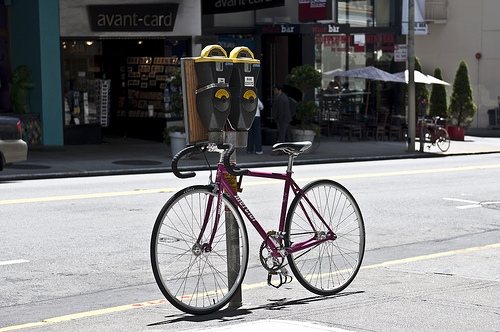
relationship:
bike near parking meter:
[149, 138, 367, 317] [192, 42, 263, 309]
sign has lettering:
[84, 2, 180, 33] [97, 14, 173, 29]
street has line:
[1, 150, 499, 329] [0, 162, 499, 205]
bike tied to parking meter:
[149, 138, 367, 317] [192, 42, 263, 309]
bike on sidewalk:
[149, 138, 367, 317] [2, 238, 499, 329]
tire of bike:
[284, 178, 366, 297] [149, 138, 367, 317]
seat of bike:
[273, 138, 314, 155] [149, 138, 367, 317]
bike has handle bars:
[149, 138, 367, 317] [171, 140, 251, 178]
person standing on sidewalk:
[269, 84, 296, 154] [0, 125, 499, 179]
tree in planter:
[446, 60, 476, 127] [444, 124, 469, 141]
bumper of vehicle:
[0, 139, 30, 168] [0, 115, 31, 172]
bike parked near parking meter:
[149, 138, 367, 317] [192, 42, 263, 309]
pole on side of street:
[406, 0, 418, 157] [1, 150, 499, 329]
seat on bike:
[273, 138, 314, 155] [149, 138, 367, 317]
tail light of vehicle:
[16, 120, 25, 136] [0, 115, 31, 172]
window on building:
[107, 37, 192, 120] [9, 1, 212, 147]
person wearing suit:
[269, 84, 296, 154] [269, 92, 292, 126]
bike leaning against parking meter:
[149, 138, 367, 317] [192, 42, 263, 309]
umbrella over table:
[335, 66, 407, 86] [352, 115, 386, 133]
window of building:
[107, 37, 192, 120] [9, 1, 212, 147]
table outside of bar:
[352, 115, 386, 133] [218, 2, 406, 135]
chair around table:
[367, 109, 391, 140] [352, 115, 386, 133]